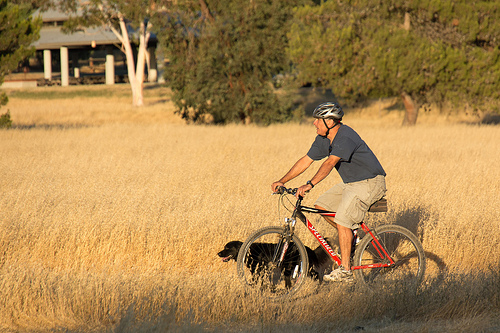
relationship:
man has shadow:
[269, 100, 388, 284] [330, 198, 434, 295]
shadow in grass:
[330, 198, 434, 295] [3, 94, 499, 331]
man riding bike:
[269, 100, 388, 284] [234, 182, 427, 298]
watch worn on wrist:
[305, 179, 317, 191] [305, 179, 317, 190]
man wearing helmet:
[269, 100, 388, 284] [311, 100, 346, 122]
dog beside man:
[217, 240, 332, 287] [269, 100, 388, 284]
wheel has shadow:
[352, 221, 428, 300] [330, 200, 449, 298]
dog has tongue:
[217, 240, 332, 287] [219, 255, 231, 263]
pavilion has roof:
[33, 26, 167, 90] [26, 28, 142, 42]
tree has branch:
[283, 3, 499, 124] [396, 8, 414, 41]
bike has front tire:
[234, 182, 427, 298] [236, 224, 311, 299]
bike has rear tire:
[234, 182, 427, 298] [352, 221, 428, 300]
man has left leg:
[269, 100, 388, 284] [336, 181, 366, 272]